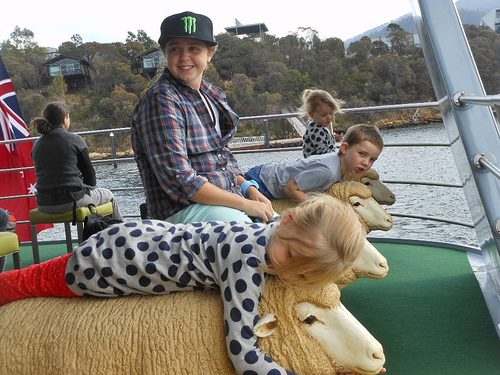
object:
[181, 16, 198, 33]
logo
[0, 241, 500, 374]
ground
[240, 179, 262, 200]
watch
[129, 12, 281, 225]
woman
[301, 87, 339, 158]
kid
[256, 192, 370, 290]
hair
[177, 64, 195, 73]
smile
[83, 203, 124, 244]
backpack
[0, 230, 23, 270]
seat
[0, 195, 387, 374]
child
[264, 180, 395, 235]
statue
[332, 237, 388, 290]
statue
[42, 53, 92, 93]
house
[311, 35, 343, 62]
tree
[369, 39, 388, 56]
tree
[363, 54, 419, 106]
tree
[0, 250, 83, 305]
pants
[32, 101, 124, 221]
woman/bench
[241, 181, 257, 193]
wrist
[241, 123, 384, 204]
boy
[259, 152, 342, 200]
t-shirt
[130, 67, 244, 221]
shirt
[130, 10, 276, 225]
person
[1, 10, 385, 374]
family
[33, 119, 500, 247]
water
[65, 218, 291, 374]
shirt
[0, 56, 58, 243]
flag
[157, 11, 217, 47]
ballcap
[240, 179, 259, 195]
wristband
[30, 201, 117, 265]
bench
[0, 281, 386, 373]
sheep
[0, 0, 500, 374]
boat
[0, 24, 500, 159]
hillside